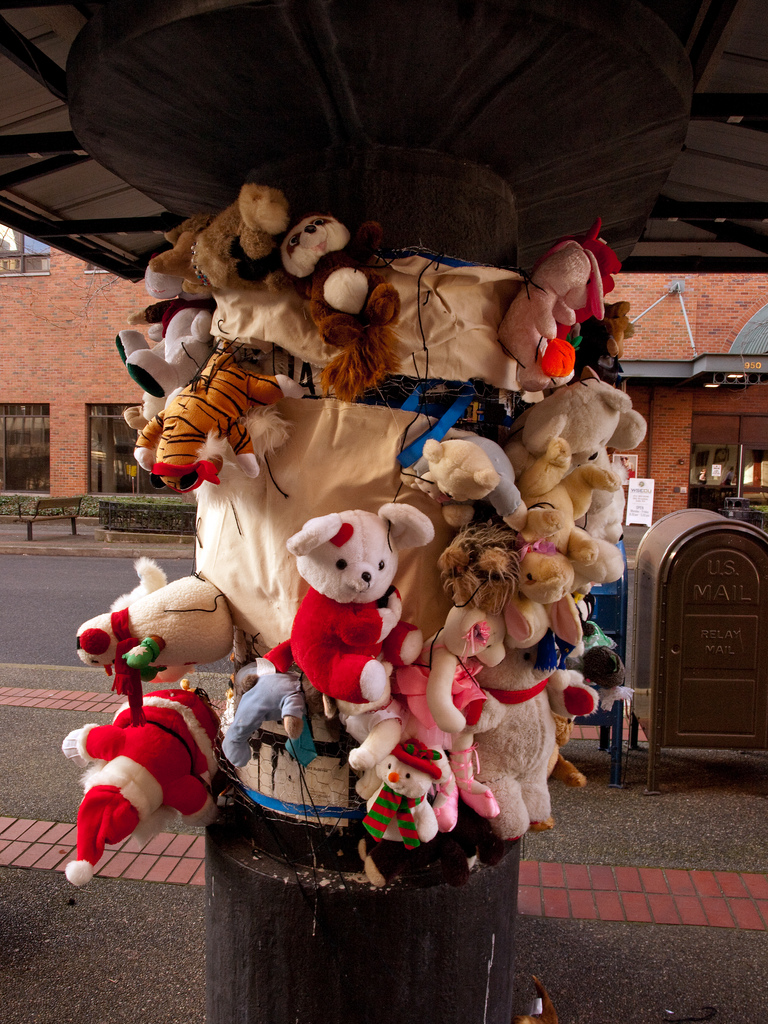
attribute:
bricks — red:
[5, 279, 133, 398]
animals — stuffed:
[69, 154, 653, 1016]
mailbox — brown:
[624, 503, 761, 812]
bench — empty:
[5, 487, 90, 538]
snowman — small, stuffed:
[363, 739, 439, 842]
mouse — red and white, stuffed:
[272, 502, 431, 700]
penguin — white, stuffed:
[71, 568, 234, 677]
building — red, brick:
[2, 233, 162, 512]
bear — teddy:
[162, 220, 761, 619]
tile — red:
[560, 826, 713, 918]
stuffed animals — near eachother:
[141, 243, 596, 887]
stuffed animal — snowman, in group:
[358, 727, 445, 854]